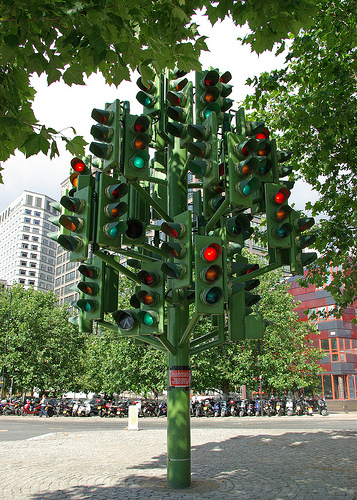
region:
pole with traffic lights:
[128, 280, 204, 481]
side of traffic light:
[227, 278, 268, 343]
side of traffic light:
[77, 261, 109, 337]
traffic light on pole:
[131, 263, 164, 336]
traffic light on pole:
[55, 192, 88, 257]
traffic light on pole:
[181, 59, 220, 126]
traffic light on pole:
[217, 142, 251, 218]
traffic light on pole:
[93, 124, 158, 198]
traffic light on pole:
[228, 111, 274, 174]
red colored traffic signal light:
[203, 246, 219, 262]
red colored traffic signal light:
[274, 190, 285, 204]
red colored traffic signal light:
[298, 219, 306, 231]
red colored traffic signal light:
[239, 142, 249, 158]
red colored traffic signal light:
[256, 128, 270, 142]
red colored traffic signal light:
[203, 75, 218, 87]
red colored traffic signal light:
[135, 119, 147, 134]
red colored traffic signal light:
[96, 112, 110, 122]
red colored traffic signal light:
[70, 159, 87, 171]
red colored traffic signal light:
[139, 270, 155, 285]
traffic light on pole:
[236, 276, 261, 347]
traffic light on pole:
[290, 218, 319, 295]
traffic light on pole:
[79, 257, 106, 330]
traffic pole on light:
[101, 165, 133, 246]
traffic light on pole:
[229, 139, 302, 218]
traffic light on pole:
[116, 240, 196, 332]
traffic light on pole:
[78, 85, 161, 156]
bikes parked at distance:
[6, 396, 116, 415]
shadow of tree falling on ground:
[230, 434, 308, 494]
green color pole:
[169, 356, 191, 487]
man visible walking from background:
[40, 394, 48, 415]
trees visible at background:
[9, 299, 59, 379]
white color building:
[5, 191, 45, 284]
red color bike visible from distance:
[22, 400, 38, 414]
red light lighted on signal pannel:
[201, 245, 221, 260]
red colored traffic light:
[202, 250, 218, 261]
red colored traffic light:
[273, 187, 289, 208]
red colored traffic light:
[254, 129, 268, 141]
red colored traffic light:
[234, 139, 251, 157]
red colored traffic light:
[202, 74, 214, 87]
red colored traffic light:
[135, 267, 154, 284]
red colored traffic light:
[163, 221, 186, 240]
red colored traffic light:
[70, 155, 85, 174]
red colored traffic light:
[63, 196, 81, 211]